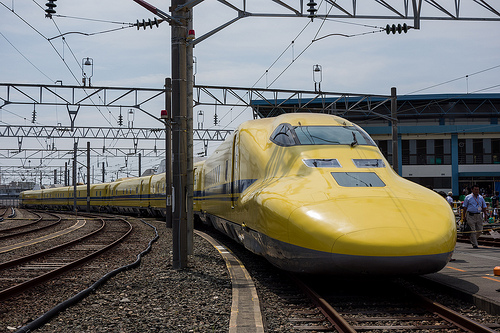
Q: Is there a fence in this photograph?
A: No, there are no fences.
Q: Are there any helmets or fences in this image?
A: No, there are no fences or helmets.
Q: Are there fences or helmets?
A: No, there are no fences or helmets.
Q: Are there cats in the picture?
A: No, there are no cats.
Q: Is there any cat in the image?
A: No, there are no cats.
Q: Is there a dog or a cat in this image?
A: No, there are no cats or dogs.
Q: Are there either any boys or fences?
A: No, there are no fences or boys.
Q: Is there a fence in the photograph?
A: No, there are no fences.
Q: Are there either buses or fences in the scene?
A: No, there are no fences or buses.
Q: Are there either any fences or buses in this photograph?
A: No, there are no fences or buses.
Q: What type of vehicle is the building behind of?
A: The building is behind the train.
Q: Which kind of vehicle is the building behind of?
A: The building is behind the train.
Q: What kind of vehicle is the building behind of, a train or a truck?
A: The building is behind a train.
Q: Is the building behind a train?
A: Yes, the building is behind a train.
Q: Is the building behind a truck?
A: No, the building is behind a train.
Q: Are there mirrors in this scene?
A: No, there are no mirrors.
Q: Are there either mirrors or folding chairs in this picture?
A: No, there are no mirrors or folding chairs.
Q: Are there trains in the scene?
A: Yes, there is a train.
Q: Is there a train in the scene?
A: Yes, there is a train.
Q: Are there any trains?
A: Yes, there is a train.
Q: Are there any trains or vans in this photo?
A: Yes, there is a train.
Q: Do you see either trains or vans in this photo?
A: Yes, there is a train.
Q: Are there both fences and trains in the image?
A: No, there is a train but no fences.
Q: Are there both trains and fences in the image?
A: No, there is a train but no fences.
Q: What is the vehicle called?
A: The vehicle is a train.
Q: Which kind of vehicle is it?
A: The vehicle is a train.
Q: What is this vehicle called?
A: This is a train.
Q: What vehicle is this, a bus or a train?
A: This is a train.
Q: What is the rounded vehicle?
A: The vehicle is a train.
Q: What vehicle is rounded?
A: The vehicle is a train.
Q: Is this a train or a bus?
A: This is a train.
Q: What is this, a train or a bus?
A: This is a train.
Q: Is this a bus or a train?
A: This is a train.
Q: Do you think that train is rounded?
A: Yes, the train is rounded.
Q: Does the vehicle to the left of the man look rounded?
A: Yes, the train is rounded.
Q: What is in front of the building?
A: The train is in front of the building.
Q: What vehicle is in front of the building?
A: The vehicle is a train.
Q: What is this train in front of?
A: The train is in front of the building.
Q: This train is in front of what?
A: The train is in front of the building.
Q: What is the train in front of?
A: The train is in front of the building.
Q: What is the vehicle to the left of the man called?
A: The vehicle is a train.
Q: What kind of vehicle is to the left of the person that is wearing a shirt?
A: The vehicle is a train.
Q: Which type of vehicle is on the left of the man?
A: The vehicle is a train.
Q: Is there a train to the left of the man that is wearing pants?
A: Yes, there is a train to the left of the man.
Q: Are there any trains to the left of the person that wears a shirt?
A: Yes, there is a train to the left of the man.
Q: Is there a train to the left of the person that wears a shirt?
A: Yes, there is a train to the left of the man.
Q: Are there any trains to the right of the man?
A: No, the train is to the left of the man.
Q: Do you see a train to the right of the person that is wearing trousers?
A: No, the train is to the left of the man.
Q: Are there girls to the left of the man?
A: No, there is a train to the left of the man.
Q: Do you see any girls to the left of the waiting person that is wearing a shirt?
A: No, there is a train to the left of the man.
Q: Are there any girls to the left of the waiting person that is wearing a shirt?
A: No, there is a train to the left of the man.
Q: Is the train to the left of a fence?
A: No, the train is to the left of the man.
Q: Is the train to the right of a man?
A: No, the train is to the left of a man.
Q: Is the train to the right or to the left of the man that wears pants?
A: The train is to the left of the man.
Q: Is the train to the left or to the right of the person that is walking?
A: The train is to the left of the man.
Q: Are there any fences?
A: No, there are no fences.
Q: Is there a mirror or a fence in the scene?
A: No, there are no fences or mirrors.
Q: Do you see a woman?
A: No, there are no women.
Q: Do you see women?
A: No, there are no women.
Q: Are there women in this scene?
A: No, there are no women.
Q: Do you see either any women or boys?
A: No, there are no women or boys.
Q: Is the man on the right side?
A: Yes, the man is on the right of the image.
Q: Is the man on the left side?
A: No, the man is on the right of the image.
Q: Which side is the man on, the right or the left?
A: The man is on the right of the image.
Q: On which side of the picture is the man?
A: The man is on the right of the image.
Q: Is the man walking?
A: Yes, the man is walking.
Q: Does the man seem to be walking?
A: Yes, the man is walking.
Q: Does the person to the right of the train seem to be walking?
A: Yes, the man is walking.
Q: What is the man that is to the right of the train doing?
A: The man is walking.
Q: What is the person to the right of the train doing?
A: The man is walking.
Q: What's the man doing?
A: The man is walking.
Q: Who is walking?
A: The man is walking.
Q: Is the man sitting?
A: No, the man is walking.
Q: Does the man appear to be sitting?
A: No, the man is walking.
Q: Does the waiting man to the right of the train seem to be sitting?
A: No, the man is walking.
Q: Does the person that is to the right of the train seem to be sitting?
A: No, the man is walking.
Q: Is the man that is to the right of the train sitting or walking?
A: The man is walking.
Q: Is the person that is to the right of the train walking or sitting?
A: The man is walking.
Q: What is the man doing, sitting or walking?
A: The man is walking.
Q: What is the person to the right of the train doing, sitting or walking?
A: The man is walking.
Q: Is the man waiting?
A: Yes, the man is waiting.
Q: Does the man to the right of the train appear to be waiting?
A: Yes, the man is waiting.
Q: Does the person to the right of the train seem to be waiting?
A: Yes, the man is waiting.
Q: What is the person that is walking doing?
A: The man is waiting.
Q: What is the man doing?
A: The man is waiting.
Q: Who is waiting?
A: The man is waiting.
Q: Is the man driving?
A: No, the man is waiting.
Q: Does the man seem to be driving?
A: No, the man is waiting.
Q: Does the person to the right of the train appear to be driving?
A: No, the man is waiting.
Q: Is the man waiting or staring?
A: The man is waiting.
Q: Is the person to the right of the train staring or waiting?
A: The man is waiting.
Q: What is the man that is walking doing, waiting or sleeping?
A: The man is waiting.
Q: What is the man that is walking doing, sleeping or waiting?
A: The man is waiting.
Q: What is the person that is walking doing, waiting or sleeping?
A: The man is waiting.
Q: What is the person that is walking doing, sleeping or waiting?
A: The man is waiting.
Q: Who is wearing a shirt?
A: The man is wearing a shirt.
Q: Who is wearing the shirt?
A: The man is wearing a shirt.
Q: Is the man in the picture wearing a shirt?
A: Yes, the man is wearing a shirt.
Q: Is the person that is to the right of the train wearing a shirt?
A: Yes, the man is wearing a shirt.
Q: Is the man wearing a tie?
A: No, the man is wearing a shirt.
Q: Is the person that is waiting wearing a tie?
A: No, the man is wearing a shirt.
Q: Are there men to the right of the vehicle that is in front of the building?
A: Yes, there is a man to the right of the train.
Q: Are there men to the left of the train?
A: No, the man is to the right of the train.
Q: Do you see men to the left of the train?
A: No, the man is to the right of the train.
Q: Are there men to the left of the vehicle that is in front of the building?
A: No, the man is to the right of the train.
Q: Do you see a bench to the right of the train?
A: No, there is a man to the right of the train.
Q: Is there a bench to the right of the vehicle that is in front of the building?
A: No, there is a man to the right of the train.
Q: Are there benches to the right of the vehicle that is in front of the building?
A: No, there is a man to the right of the train.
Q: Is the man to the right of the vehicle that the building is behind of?
A: Yes, the man is to the right of the train.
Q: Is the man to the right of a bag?
A: No, the man is to the right of the train.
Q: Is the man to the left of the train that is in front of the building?
A: No, the man is to the right of the train.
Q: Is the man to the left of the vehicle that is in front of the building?
A: No, the man is to the right of the train.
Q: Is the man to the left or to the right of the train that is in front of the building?
A: The man is to the right of the train.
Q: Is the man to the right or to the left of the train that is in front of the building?
A: The man is to the right of the train.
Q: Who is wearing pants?
A: The man is wearing pants.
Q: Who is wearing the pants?
A: The man is wearing pants.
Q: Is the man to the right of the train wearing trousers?
A: Yes, the man is wearing trousers.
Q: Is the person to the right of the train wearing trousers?
A: Yes, the man is wearing trousers.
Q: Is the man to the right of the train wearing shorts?
A: No, the man is wearing trousers.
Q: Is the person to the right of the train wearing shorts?
A: No, the man is wearing trousers.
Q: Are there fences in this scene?
A: No, there are no fences.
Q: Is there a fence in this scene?
A: No, there are no fences.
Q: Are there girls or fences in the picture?
A: No, there are no fences or girls.